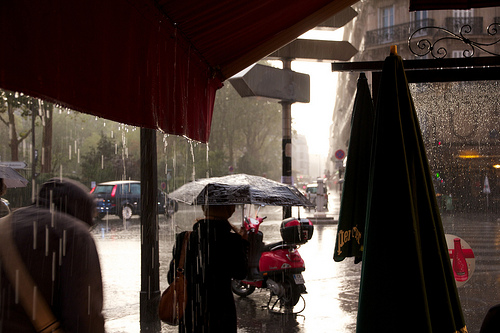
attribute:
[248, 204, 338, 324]
motorbike — Red 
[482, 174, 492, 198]
umbrella — white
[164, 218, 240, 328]
coat — black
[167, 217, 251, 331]
jacket — black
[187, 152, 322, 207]
umbrella — black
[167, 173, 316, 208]
umbrella — black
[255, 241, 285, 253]
seat — black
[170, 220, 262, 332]
jacket — black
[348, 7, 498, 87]
balcony — black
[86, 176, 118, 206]
tail lights — active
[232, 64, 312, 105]
sign — arrow shaped